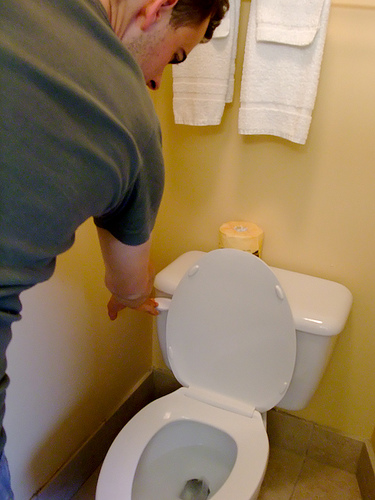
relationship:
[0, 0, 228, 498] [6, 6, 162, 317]
man wears shirt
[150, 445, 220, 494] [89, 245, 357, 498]
water in toilet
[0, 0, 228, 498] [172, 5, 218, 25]
man has hair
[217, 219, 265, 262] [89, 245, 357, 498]
toilet paper on toilet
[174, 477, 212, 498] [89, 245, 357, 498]
hole in toilet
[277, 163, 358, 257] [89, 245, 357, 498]
wall behind toilet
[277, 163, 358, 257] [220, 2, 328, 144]
wall behind towels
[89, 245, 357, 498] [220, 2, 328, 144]
toilet under towels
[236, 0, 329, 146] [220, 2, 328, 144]
towels on towels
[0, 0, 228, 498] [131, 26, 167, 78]
man has facial hair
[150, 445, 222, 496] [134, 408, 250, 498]
water in bowl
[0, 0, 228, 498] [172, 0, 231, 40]
man has hair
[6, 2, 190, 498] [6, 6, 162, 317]
man has shirt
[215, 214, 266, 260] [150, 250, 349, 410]
roll on top of tank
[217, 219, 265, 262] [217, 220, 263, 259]
toilet paper wrapped in wrapper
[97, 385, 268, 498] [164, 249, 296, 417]
toilet seat has lid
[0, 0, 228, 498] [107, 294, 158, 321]
man has hand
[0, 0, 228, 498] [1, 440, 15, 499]
man has jeans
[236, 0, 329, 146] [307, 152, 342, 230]
towels hanging wall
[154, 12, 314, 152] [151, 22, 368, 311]
towels on rack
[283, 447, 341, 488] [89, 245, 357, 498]
tile floor by toilet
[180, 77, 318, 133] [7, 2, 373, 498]
towels in bathroom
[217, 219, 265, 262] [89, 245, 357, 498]
toilet paper sitting on toilet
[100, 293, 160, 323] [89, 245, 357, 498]
hand flushing toilet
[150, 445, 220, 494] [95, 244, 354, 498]
water in toilet bowl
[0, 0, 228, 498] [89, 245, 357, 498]
man by toilet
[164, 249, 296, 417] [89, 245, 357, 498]
lid of toilet